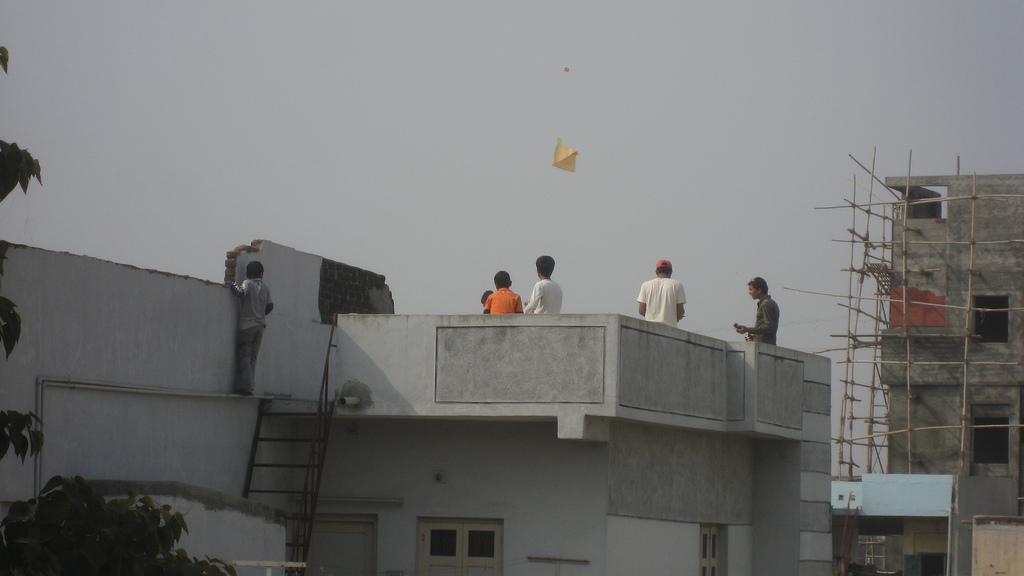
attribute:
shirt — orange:
[485, 272, 524, 310]